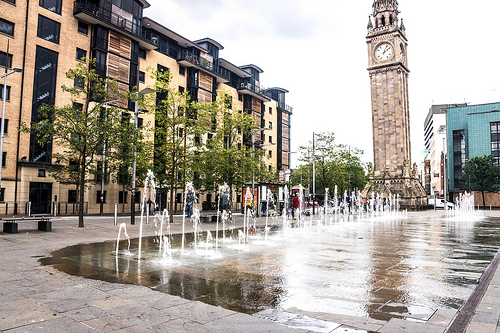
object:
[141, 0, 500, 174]
sky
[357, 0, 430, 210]
clock tower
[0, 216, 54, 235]
bench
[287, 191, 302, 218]
people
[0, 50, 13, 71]
windows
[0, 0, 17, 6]
windows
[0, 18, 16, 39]
windows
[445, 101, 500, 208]
building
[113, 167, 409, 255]
fountains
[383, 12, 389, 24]
spires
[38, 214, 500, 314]
water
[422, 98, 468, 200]
building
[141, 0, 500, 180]
clouds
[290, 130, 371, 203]
trees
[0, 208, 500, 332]
ground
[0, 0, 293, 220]
building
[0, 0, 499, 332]
plaza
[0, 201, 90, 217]
fence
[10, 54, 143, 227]
trees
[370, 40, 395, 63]
clock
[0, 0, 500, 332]
plaza area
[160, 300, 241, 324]
stones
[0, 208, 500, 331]
land